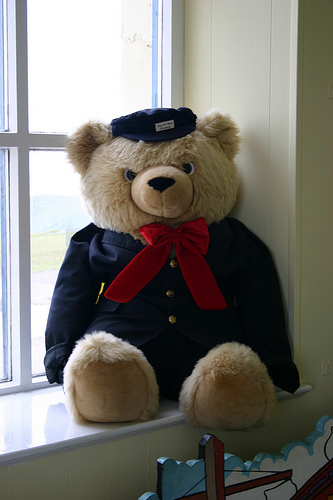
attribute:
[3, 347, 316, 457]
ledge — white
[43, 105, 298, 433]
teddy bear — tan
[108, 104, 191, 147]
hat — blue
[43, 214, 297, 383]
jacket — Dark blue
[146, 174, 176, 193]
nose — black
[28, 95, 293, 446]
teddy bear — brown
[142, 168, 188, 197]
nose — black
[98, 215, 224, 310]
bow — red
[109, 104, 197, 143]
cap — navy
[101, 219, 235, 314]
ribbon — red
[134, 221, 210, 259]
bow — red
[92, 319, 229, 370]
shorts — blue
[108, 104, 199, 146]
hat — Navy blue, blue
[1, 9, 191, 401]
frame — white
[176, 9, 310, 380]
wall — white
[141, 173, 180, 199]
nose — black